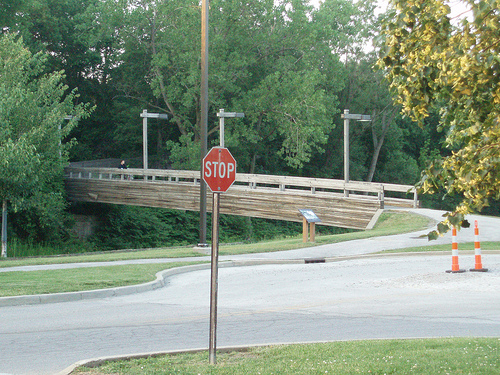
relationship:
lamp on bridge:
[333, 94, 373, 199] [213, 164, 377, 225]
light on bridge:
[343, 106, 380, 137] [213, 164, 377, 225]